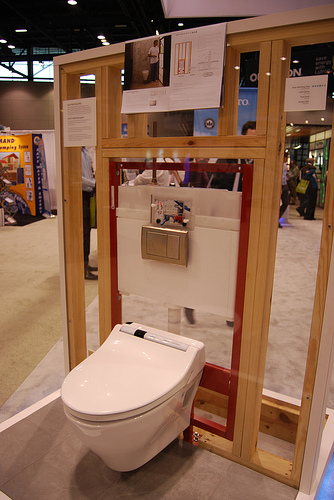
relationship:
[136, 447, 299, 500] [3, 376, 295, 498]
tile in floor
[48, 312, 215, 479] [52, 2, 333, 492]
toilet on display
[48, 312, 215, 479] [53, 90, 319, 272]
toilet behind wood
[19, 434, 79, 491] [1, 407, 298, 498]
tile on floor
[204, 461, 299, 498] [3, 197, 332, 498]
tile on floor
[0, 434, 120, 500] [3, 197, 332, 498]
tile on floor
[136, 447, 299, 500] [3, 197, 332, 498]
tile on floor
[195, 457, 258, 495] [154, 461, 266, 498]
tile on floor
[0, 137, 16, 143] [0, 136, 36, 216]
letter on sign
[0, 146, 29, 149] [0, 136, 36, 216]
letter on sign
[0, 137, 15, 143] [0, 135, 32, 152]
letters on sign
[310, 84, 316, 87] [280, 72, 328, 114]
letter on sign